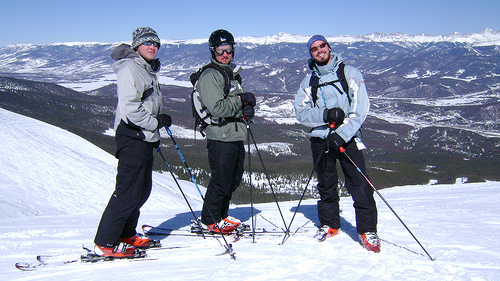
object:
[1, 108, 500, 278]
slope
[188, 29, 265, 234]
man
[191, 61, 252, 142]
jacket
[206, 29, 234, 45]
helmet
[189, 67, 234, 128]
backpack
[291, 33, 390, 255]
man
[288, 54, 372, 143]
jacket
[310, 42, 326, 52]
sunglasses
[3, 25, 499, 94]
mountains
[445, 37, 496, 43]
background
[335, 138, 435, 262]
ski poles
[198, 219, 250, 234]
ski boots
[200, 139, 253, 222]
pants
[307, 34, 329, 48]
beanie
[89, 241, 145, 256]
ski boots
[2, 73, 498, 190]
valley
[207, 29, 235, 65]
head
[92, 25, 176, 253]
man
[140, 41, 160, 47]
sunglasses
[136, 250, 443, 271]
snow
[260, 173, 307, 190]
trees